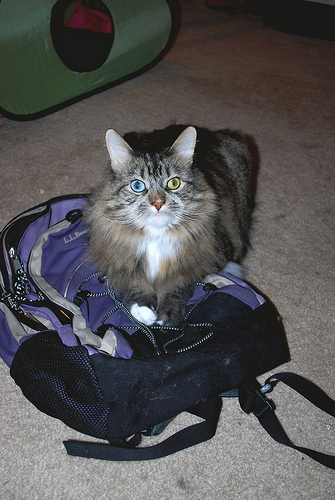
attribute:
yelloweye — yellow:
[164, 174, 183, 190]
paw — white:
[128, 300, 157, 323]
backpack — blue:
[9, 192, 295, 442]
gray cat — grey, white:
[78, 123, 255, 305]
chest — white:
[137, 230, 173, 280]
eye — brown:
[160, 173, 185, 189]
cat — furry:
[84, 115, 252, 328]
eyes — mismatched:
[129, 173, 180, 192]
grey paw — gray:
[156, 299, 183, 326]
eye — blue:
[129, 178, 144, 193]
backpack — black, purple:
[0, 189, 335, 468]